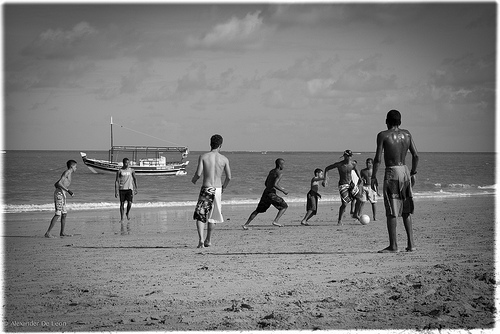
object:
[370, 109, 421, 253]
black male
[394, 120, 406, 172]
wall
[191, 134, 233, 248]
male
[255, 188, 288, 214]
shorts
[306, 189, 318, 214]
shorts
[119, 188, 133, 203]
shorts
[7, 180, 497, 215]
wave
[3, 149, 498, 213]
ocean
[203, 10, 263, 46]
white clouds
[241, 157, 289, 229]
male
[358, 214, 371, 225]
ball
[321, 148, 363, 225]
male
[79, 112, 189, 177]
boat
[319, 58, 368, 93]
ground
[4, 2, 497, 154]
sky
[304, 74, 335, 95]
white clouds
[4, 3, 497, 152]
blue sky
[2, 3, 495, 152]
clouds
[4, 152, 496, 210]
water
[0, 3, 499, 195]
background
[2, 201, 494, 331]
beach